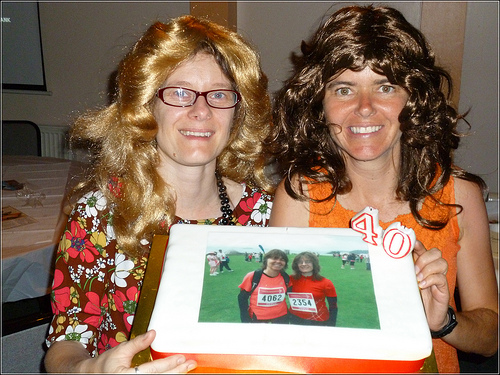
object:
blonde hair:
[66, 15, 275, 257]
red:
[259, 279, 284, 285]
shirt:
[237, 270, 290, 320]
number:
[258, 295, 285, 304]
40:
[351, 207, 416, 259]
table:
[0, 153, 74, 261]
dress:
[307, 158, 461, 375]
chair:
[0, 120, 42, 156]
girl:
[262, 3, 499, 374]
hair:
[253, 3, 492, 231]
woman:
[239, 250, 292, 325]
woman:
[286, 250, 339, 327]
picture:
[197, 239, 381, 330]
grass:
[205, 278, 239, 315]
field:
[196, 251, 373, 325]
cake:
[144, 222, 436, 374]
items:
[0, 205, 39, 229]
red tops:
[238, 272, 336, 321]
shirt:
[288, 275, 336, 320]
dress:
[42, 184, 275, 355]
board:
[0, 1, 50, 95]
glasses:
[155, 85, 241, 107]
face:
[154, 66, 233, 158]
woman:
[40, 13, 270, 375]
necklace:
[212, 171, 234, 225]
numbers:
[287, 296, 312, 308]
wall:
[49, 11, 104, 83]